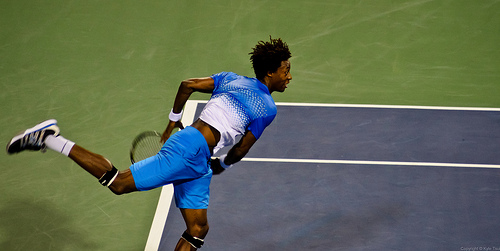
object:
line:
[141, 98, 199, 250]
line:
[239, 152, 500, 175]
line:
[270, 99, 500, 114]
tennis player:
[5, 34, 292, 250]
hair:
[247, 37, 292, 81]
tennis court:
[0, 0, 500, 250]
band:
[98, 162, 120, 189]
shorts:
[129, 125, 213, 209]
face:
[274, 59, 293, 93]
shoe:
[6, 118, 61, 155]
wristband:
[167, 107, 182, 122]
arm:
[167, 72, 227, 119]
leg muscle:
[83, 145, 113, 175]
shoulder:
[254, 101, 277, 125]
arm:
[223, 113, 276, 162]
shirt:
[197, 71, 278, 159]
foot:
[6, 119, 62, 155]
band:
[179, 229, 208, 249]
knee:
[183, 220, 211, 235]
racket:
[129, 129, 169, 164]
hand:
[159, 120, 185, 144]